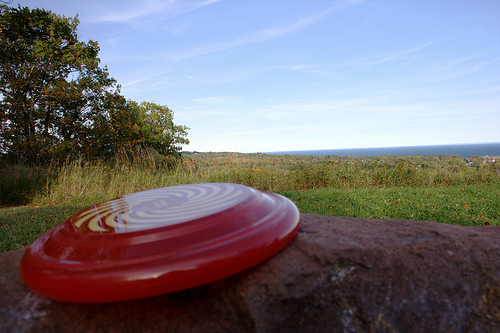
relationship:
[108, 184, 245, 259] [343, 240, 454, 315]
frisbee on rock